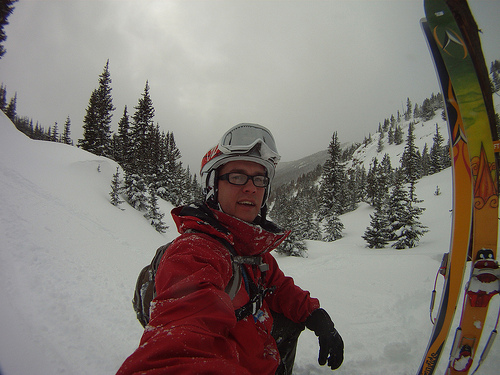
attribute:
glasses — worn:
[221, 173, 300, 196]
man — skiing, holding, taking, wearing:
[132, 147, 302, 341]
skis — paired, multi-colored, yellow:
[427, 44, 495, 224]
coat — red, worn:
[181, 245, 278, 322]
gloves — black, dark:
[298, 279, 350, 356]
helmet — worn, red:
[196, 135, 233, 177]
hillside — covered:
[32, 136, 129, 231]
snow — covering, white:
[39, 193, 139, 346]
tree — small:
[110, 175, 141, 217]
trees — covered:
[294, 190, 454, 253]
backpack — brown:
[126, 255, 181, 344]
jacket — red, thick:
[156, 200, 267, 350]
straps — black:
[224, 261, 274, 312]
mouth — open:
[236, 186, 274, 211]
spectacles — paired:
[213, 168, 276, 185]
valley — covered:
[110, 105, 485, 290]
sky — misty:
[113, 71, 242, 154]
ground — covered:
[48, 208, 105, 305]